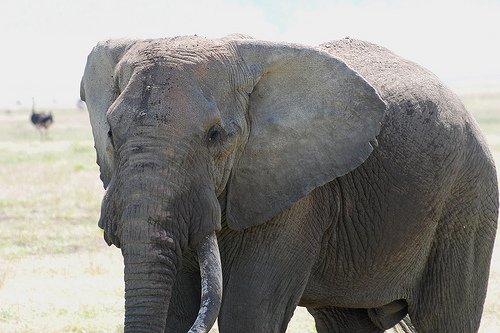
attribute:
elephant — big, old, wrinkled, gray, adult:
[80, 35, 500, 331]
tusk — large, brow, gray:
[184, 229, 223, 331]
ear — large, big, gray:
[225, 41, 387, 231]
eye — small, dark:
[210, 128, 221, 142]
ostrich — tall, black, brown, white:
[30, 95, 47, 141]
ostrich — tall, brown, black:
[38, 98, 58, 141]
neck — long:
[31, 100, 37, 112]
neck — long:
[46, 101, 54, 115]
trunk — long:
[113, 149, 193, 332]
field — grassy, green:
[2, 105, 126, 332]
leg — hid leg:
[406, 289, 487, 331]